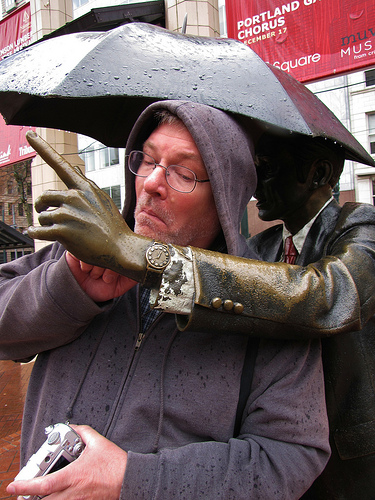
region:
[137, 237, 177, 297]
watch on copper statue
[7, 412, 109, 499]
digital camera being held by man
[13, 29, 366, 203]
umbrella made out of metal as part of sculpture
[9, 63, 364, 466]
man with gray sweatshirt with zipper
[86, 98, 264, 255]
man with glasses and gray sweatshirt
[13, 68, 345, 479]
man joking around with statue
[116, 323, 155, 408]
zipper on gray sweatshirt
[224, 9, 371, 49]
red and white sign hanging on building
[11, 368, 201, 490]
man holding digital camera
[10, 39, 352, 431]
rainy day in Portalnd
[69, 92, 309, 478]
Caucasian man with glasses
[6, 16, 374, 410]
Caucasian man with statue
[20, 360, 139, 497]
Caucasian man with a camera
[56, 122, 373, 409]
a statue with a watch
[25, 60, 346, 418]
a Caucasian man with an umbrella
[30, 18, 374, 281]
Caucasian man in New York City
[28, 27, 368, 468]
Older man in a gray hoodie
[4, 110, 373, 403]
Man with red skin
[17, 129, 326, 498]
gray hoodie with rain on it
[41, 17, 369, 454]
man in an urban city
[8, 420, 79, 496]
the man has a camera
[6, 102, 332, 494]
the man is wearing a sweater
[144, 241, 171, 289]
the statue has a watch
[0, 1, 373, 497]
it is raining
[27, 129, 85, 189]
the statue points his finger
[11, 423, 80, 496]
the camera is gray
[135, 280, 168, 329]
the man wears a plaid shirt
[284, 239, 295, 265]
the statue has a tie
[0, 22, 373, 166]
the statue has an umbrella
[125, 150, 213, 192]
the man wears glasses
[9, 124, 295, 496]
man holding a silver camera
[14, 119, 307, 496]
man wearing a black hoodie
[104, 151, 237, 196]
man wearing wire rim glasses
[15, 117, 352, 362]
bronze statue of a man pointing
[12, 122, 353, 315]
bronze statue of a man wearing a watch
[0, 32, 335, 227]
bronze statue of a man holding a black umbrella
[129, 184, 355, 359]
bronze statue of a man wearing a dress suit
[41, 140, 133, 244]
windows in an apartment building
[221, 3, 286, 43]
the letter P on the side of a building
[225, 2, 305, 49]
the letter o on the side of a building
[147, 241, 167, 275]
a watch on the hand of a statue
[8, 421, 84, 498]
A digital camera in someone's hand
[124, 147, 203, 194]
glasses on the man's face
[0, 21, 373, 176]
A wet black umbrella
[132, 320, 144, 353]
A zipper on a hooded sweater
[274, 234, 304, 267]
The statue is wearing a tie.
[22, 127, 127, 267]
The statue is gesturing with this hand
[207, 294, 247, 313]
buttons on the sleeve of a statue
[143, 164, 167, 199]
the man's nose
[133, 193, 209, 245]
A stubbly gray beard on the man's face